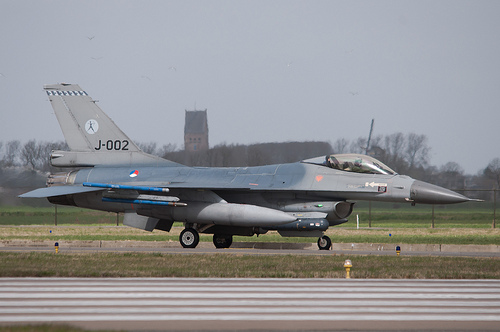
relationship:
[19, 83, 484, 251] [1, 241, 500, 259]
airplane sitting on tarmac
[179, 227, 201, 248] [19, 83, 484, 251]
tire of airplane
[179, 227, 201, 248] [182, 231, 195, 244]
tire with wheel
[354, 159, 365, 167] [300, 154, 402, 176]
pilot sitting in cockpit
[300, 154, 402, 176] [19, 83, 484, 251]
cockpit of airplane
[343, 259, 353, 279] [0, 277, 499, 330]
marking alongside runway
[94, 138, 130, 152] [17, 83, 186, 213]
numbers on tail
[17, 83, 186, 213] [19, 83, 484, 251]
tail of airplane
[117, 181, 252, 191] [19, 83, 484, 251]
wing of airplane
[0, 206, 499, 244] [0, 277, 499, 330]
grass located by runway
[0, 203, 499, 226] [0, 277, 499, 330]
fence next to runway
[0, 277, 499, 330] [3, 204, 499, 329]
runway at airport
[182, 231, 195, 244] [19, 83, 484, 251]
wheel of airplane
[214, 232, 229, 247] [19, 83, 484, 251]
wheel of airplane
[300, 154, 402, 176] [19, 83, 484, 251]
cockpit covering airplane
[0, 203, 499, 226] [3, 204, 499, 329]
fence on edge of airport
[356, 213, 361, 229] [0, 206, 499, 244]
pole sticking out of grass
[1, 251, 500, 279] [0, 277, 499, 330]
grass alongside runway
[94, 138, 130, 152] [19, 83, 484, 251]
numbers written on airplane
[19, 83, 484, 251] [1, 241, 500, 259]
airplane parked on tarmac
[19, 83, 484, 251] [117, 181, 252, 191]
airplane with wing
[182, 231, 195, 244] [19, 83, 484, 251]
wheel attached on airplane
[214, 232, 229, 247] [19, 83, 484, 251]
wheel attached on airplane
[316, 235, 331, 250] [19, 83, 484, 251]
front wheel attached on airplane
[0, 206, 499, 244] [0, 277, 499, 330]
grass behind runway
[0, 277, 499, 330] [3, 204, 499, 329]
runway of airport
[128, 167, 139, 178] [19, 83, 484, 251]
decal on side of airplane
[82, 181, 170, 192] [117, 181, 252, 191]
rod above wing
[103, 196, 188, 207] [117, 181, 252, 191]
rod below wing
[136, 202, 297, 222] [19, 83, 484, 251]
cylinder to side of airplane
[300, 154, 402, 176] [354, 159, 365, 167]
cockpit covering pilot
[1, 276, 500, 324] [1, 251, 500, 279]
lines next to grass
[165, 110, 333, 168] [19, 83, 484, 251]
building behind airplane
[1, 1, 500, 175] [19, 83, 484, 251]
sky behind airplane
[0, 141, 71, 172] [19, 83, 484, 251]
trees behind airplane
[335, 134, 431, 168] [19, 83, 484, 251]
trees behind airplane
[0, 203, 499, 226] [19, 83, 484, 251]
fence behind airplane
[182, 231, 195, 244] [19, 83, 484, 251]
wheel under airplane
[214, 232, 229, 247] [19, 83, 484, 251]
wheel under airplane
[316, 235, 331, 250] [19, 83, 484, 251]
front wheel under airplane